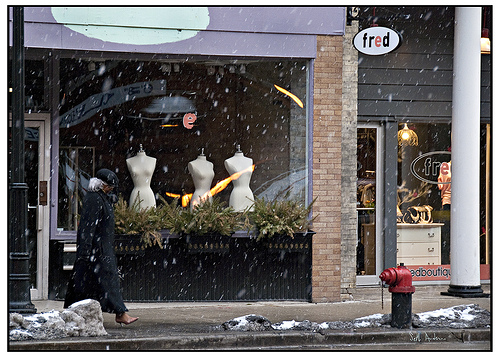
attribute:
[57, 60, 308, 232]
window — glass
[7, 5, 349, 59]
awning — purple, white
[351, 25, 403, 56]
shop sign — white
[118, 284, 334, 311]
snow — melting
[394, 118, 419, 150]
streetlight — black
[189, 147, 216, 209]
mannequin — bare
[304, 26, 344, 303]
wall — red, brick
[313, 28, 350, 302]
wall — red, brick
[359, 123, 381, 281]
door — glass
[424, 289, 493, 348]
snow — dirty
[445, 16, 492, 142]
column — large, white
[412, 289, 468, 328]
snow — dirty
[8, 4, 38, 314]
lamp post — black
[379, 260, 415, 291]
top — red